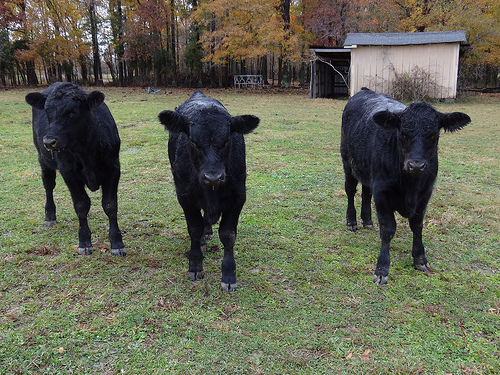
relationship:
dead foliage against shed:
[362, 62, 454, 103] [311, 30, 469, 100]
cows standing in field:
[19, 75, 466, 290] [115, 309, 450, 373]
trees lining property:
[2, 2, 498, 99] [3, 84, 498, 373]